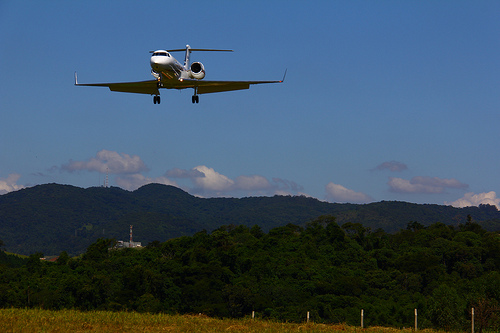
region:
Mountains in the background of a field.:
[9, 176, 497, 216]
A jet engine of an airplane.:
[186, 55, 208, 80]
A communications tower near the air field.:
[124, 218, 139, 255]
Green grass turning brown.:
[16, 317, 260, 332]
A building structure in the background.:
[34, 246, 65, 269]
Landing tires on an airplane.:
[144, 91, 202, 106]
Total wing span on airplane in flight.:
[68, 64, 296, 93]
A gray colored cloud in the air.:
[367, 158, 419, 173]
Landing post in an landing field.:
[239, 305, 494, 331]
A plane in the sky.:
[65, 38, 315, 138]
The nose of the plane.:
[153, 52, 165, 67]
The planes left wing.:
[187, 80, 310, 96]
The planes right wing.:
[71, 75, 155, 95]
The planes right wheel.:
[151, 88, 163, 110]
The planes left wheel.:
[187, 93, 200, 108]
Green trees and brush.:
[16, 209, 498, 331]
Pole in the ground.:
[125, 220, 133, 252]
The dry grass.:
[1, 311, 175, 330]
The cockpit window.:
[152, 50, 169, 57]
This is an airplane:
[43, 25, 301, 130]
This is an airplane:
[51, 38, 317, 141]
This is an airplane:
[46, 30, 301, 142]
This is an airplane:
[59, 27, 301, 140]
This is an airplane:
[65, 31, 297, 133]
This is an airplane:
[76, 35, 302, 146]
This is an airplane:
[66, 32, 303, 129]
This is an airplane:
[58, 36, 294, 121]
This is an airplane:
[55, 39, 300, 129]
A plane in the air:
[72, 43, 289, 103]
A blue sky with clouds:
[0, 1, 498, 207]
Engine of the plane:
[188, 61, 205, 78]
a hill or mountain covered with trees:
[0, 183, 498, 258]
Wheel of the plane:
[190, 95, 198, 103]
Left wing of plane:
[182, 67, 299, 95]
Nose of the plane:
[148, 50, 172, 71]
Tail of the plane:
[145, 41, 230, 62]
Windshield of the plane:
[151, 50, 169, 58]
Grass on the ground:
[0, 307, 442, 332]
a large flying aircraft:
[64, 41, 310, 126]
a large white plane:
[85, 40, 327, 112]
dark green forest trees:
[212, 208, 410, 319]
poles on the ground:
[244, 298, 475, 330]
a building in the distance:
[88, 212, 177, 265]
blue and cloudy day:
[309, 32, 459, 191]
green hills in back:
[28, 149, 230, 234]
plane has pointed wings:
[76, 40, 286, 114]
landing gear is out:
[137, 58, 215, 111]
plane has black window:
[139, 50, 199, 77]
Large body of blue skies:
[356, 15, 454, 105]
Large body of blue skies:
[314, 18, 424, 112]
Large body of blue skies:
[241, 119, 303, 154]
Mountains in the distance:
[2, 173, 494, 230]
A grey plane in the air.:
[71, 45, 288, 105]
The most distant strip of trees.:
[1, 182, 499, 260]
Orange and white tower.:
[128, 224, 133, 248]